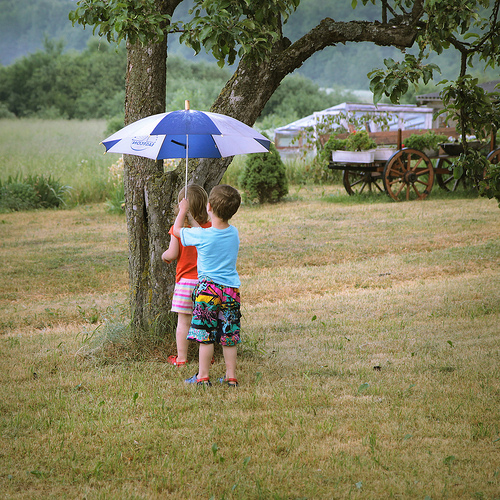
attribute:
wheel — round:
[382, 147, 433, 202]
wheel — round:
[341, 156, 387, 196]